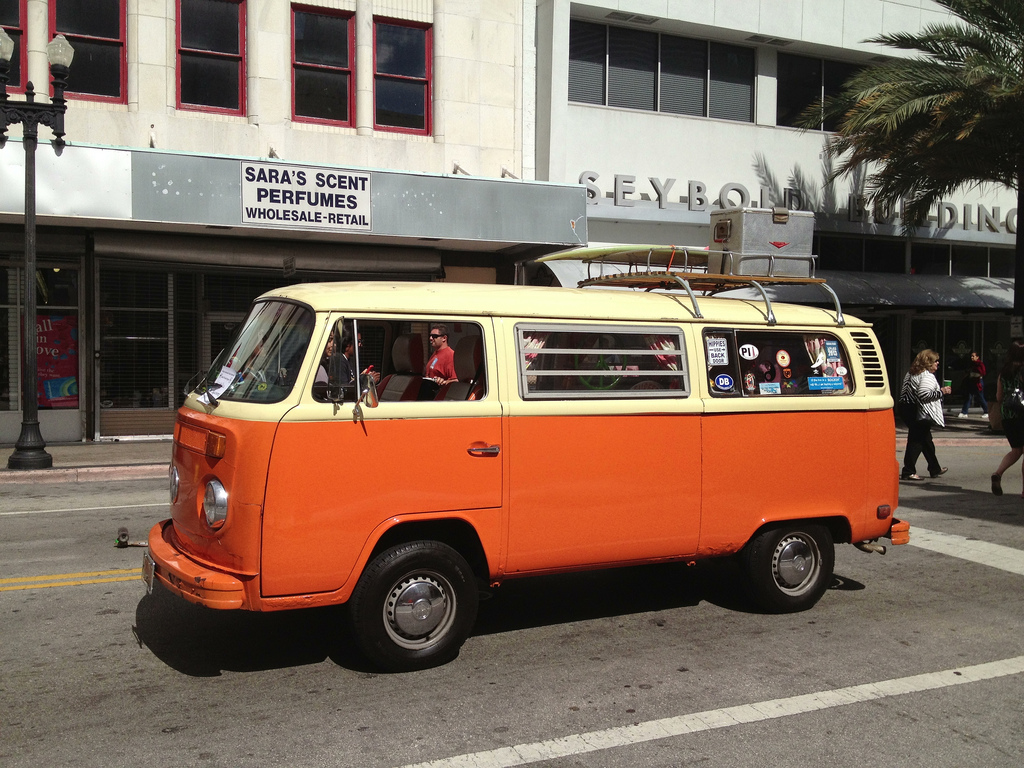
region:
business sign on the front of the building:
[243, 154, 374, 234]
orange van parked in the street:
[167, 269, 911, 633]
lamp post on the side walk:
[5, 29, 85, 486]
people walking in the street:
[893, 328, 1021, 502]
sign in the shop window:
[39, 306, 81, 414]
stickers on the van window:
[707, 329, 869, 415]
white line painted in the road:
[644, 650, 888, 756]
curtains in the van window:
[524, 326, 687, 391]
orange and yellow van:
[155, 273, 930, 635]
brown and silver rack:
[667, 246, 832, 319]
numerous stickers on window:
[683, 331, 868, 401]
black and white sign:
[222, 156, 385, 251]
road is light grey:
[484, 653, 824, 758]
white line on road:
[686, 631, 898, 726]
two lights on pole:
[3, 21, 89, 99]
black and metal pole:
[1, 78, 59, 470]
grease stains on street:
[605, 627, 723, 703]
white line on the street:
[594, 685, 800, 723]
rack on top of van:
[552, 209, 856, 320]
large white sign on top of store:
[204, 154, 397, 222]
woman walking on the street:
[890, 326, 979, 501]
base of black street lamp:
[0, 405, 73, 473]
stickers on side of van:
[692, 332, 869, 415]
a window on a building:
[28, 2, 133, 113]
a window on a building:
[161, 4, 239, 118]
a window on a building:
[274, 13, 351, 111]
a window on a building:
[362, 18, 432, 164]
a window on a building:
[659, 6, 711, 112]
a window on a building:
[714, 53, 754, 134]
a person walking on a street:
[907, 304, 959, 497]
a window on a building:
[7, 4, 27, 97]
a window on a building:
[57, 4, 125, 104]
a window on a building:
[171, 0, 248, 128]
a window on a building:
[291, 4, 349, 115]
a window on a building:
[376, 13, 425, 144]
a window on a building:
[566, 16, 618, 109]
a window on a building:
[611, 13, 657, 115]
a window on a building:
[718, 28, 758, 124]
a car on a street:
[114, 279, 921, 653]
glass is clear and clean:
[298, 64, 349, 116]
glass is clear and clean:
[359, 323, 483, 399]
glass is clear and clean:
[310, 318, 355, 402]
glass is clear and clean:
[215, 303, 308, 402]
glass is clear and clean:
[519, 326, 684, 349]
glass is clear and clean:
[519, 351, 687, 372]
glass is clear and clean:
[523, 375, 689, 394]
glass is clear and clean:
[706, 329, 859, 402]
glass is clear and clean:
[377, 76, 425, 122]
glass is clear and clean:
[374, 19, 426, 76]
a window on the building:
[552, 23, 581, 96]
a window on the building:
[605, 18, 634, 111]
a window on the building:
[675, 12, 701, 117]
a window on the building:
[696, 32, 786, 143]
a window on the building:
[763, 9, 806, 134]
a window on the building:
[386, 3, 429, 128]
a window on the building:
[295, 20, 335, 137]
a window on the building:
[207, 6, 245, 102]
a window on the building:
[64, 0, 160, 105]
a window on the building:
[134, 255, 186, 515]